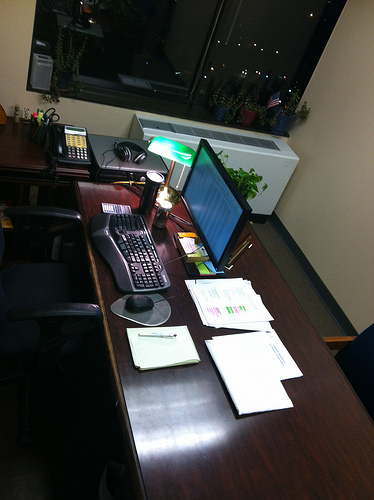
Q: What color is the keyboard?
A: Black.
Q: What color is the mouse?
A: Black.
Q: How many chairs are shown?
A: Two.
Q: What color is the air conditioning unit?
A: White.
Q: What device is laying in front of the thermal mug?
A: A calculator.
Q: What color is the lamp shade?
A: Green.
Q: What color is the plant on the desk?
A: Green.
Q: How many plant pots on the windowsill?
A: Four.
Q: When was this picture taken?
A: Late at night.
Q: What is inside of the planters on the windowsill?
A: A small plant.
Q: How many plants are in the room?
A: Five.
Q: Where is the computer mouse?
A: Next to the keyboard, on the desk.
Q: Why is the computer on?
A: The person who the office belongs to is still working.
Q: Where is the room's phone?
A: Next to the laptop, near the window.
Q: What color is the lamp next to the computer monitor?
A: Green and gold.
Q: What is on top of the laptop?
A: A pair of headphones.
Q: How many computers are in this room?
A: Two.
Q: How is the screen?
A: On.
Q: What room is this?
A: Office room.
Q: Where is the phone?
A: In the table.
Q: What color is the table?
A: Brown.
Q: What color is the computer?
A: Black.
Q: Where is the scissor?
A: In the stand.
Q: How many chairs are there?
A: Two.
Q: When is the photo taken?
A: Night time.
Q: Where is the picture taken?
A: At the office.